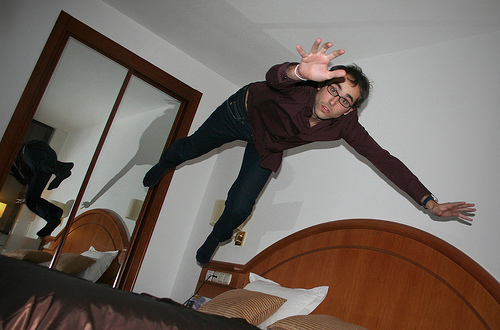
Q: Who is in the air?
A: The man.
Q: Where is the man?
A: In the air.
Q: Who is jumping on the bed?
A: A man.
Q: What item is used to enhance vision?
A: Glasses.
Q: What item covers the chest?
A: A shirt.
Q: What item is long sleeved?
A: A shirt.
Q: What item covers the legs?
A: A pant.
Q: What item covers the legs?
A: Jean pants.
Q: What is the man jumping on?
A: Bed.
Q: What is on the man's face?
A: Glasses.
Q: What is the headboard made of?
A: Wood.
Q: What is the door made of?
A: Glass.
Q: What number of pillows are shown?
A: 3.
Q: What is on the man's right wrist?
A: Watcch.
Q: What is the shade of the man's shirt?
A: Brown.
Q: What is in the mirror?
A: Reflection.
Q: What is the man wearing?
A: Jeans.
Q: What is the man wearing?
A: Pant.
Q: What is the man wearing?
A: Glasses.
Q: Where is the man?
A: In air.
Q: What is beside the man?
A: Window.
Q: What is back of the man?
A: Mirror.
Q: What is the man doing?
A: Jumping.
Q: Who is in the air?
A: The man.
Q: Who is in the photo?
A: A man.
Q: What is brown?
A: The headboard.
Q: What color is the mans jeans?
A: Blue.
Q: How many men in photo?
A: One.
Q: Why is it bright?
A: The lighting.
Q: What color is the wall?
A: White.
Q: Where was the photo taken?
A: In bedroom.